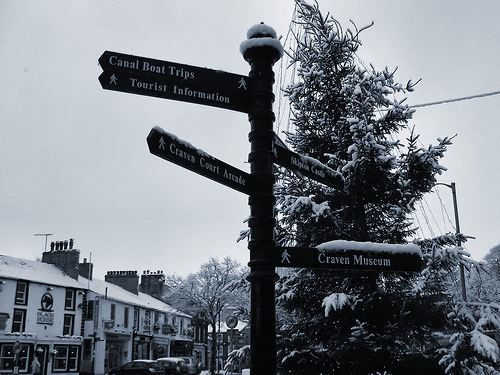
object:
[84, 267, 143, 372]
building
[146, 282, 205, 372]
building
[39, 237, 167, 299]
chimneys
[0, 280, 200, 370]
building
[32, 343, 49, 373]
door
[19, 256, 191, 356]
building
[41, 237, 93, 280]
chimney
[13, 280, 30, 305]
window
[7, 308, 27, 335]
window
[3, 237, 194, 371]
building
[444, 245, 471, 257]
snow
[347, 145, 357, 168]
snow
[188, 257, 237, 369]
trees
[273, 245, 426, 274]
sign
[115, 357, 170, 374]
car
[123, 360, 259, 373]
street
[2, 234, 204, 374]
house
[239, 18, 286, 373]
pole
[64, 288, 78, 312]
window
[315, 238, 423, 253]
snow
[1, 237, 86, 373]
building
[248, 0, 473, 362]
tree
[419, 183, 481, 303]
lightpole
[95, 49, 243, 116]
sign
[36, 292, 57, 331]
black sign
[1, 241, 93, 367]
building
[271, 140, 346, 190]
sign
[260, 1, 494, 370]
snow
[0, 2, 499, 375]
corner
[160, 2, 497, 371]
snow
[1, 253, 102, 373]
building